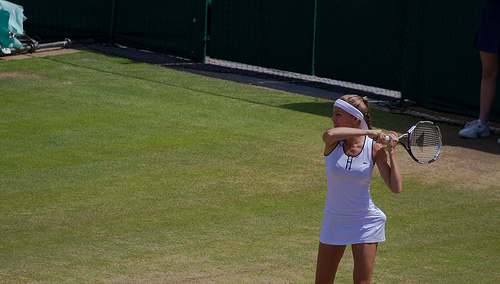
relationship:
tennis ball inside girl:
[370, 210, 387, 223] [313, 93, 402, 284]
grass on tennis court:
[7, 50, 496, 280] [2, 2, 497, 282]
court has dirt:
[2, 47, 495, 279] [383, 125, 497, 190]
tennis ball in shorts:
[375, 208, 387, 223] [316, 205, 386, 244]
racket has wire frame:
[371, 121, 442, 165] [410, 123, 442, 161]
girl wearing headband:
[313, 93, 402, 284] [319, 93, 410, 138]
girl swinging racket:
[313, 93, 402, 284] [386, 109, 468, 192]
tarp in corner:
[0, 1, 26, 54] [0, 0, 37, 56]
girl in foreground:
[313, 93, 402, 284] [4, 90, 494, 270]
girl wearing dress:
[313, 93, 402, 284] [313, 94, 403, 282]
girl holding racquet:
[313, 93, 402, 284] [395, 115, 452, 166]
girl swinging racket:
[313, 93, 402, 284] [383, 121, 445, 162]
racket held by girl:
[371, 121, 442, 165] [313, 93, 402, 284]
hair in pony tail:
[346, 109, 384, 131] [353, 88, 384, 141]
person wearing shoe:
[454, 0, 500, 146] [457, 119, 492, 139]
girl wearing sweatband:
[313, 93, 402, 284] [332, 95, 369, 125]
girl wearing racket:
[313, 93, 402, 284] [371, 121, 442, 165]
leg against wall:
[456, 44, 497, 144] [228, 17, 485, 150]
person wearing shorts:
[454, 3, 498, 143] [467, 16, 497, 55]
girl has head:
[313, 93, 402, 284] [321, 85, 373, 142]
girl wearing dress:
[313, 93, 402, 284] [324, 138, 376, 235]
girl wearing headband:
[313, 93, 402, 284] [333, 98, 368, 136]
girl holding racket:
[313, 93, 402, 284] [371, 121, 442, 165]